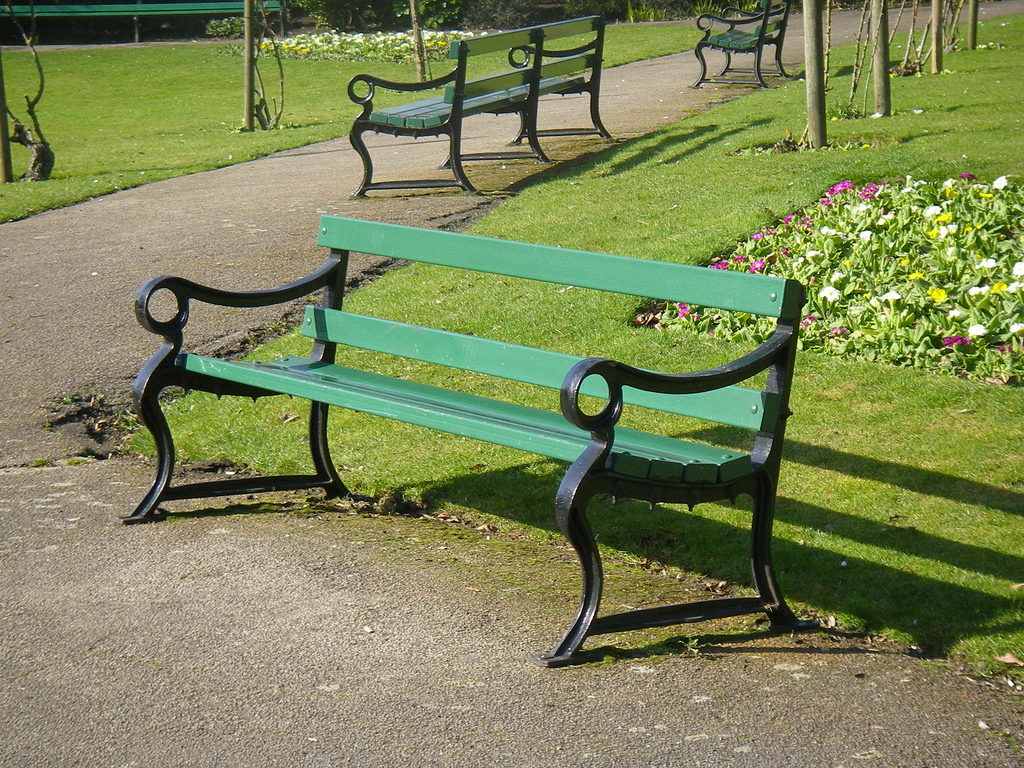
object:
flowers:
[989, 282, 1006, 295]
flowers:
[926, 288, 946, 303]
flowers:
[944, 336, 971, 348]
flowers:
[877, 289, 901, 302]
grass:
[131, 9, 1024, 679]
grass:
[0, 43, 740, 229]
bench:
[688, 0, 797, 90]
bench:
[109, 214, 819, 667]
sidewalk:
[0, 0, 1024, 768]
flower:
[829, 181, 856, 196]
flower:
[893, 305, 920, 330]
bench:
[348, 17, 619, 201]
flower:
[907, 336, 935, 360]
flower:
[877, 291, 901, 313]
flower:
[819, 286, 839, 301]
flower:
[958, 171, 978, 179]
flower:
[922, 206, 941, 218]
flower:
[941, 177, 955, 192]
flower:
[941, 224, 958, 238]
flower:
[974, 258, 996, 269]